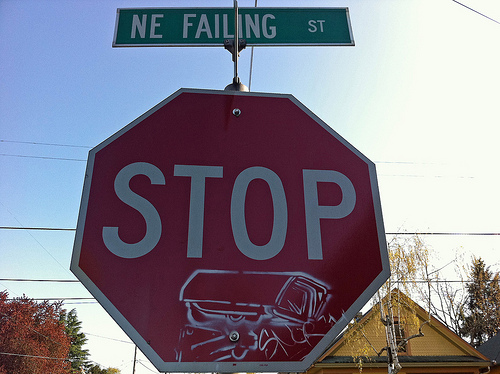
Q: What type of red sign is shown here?
A: A stop sign.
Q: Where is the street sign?
A: Above the stop sign.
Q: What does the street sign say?
A: NE Failing St.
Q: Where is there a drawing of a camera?
A: On the stop sign.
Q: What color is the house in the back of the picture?
A: Yellow.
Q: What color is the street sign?
A: Green.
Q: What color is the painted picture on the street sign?
A: White.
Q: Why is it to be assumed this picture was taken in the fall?
A: One of the trees has turned color.